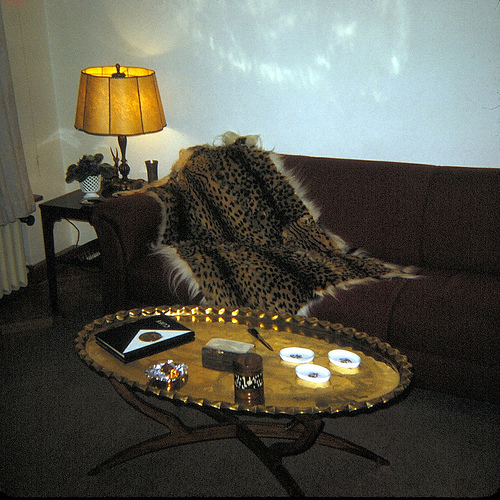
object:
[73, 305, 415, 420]
table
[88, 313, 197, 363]
book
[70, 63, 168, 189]
light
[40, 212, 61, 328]
stand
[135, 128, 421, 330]
fur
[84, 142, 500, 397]
couch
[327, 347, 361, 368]
bowl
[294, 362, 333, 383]
bowl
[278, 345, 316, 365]
bowl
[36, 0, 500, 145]
wall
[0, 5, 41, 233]
curtains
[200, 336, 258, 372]
box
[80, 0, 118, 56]
corner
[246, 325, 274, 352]
pen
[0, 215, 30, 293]
radiator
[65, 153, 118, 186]
plant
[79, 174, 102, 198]
vase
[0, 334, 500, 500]
floor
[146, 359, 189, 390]
dish